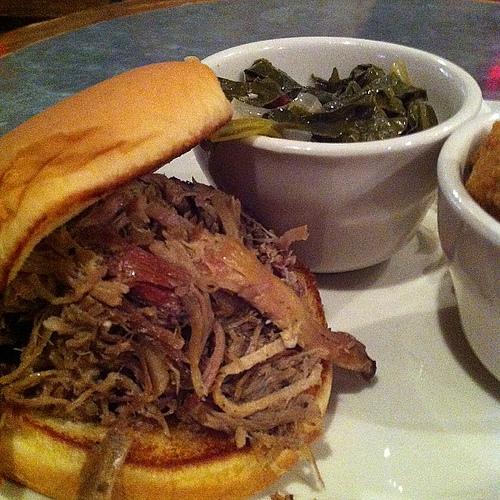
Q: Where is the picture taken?
A: Restaurant.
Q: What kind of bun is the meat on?
A: White.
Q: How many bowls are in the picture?
A: Two.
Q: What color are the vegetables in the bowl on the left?
A: Green.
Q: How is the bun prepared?
A: Toasted.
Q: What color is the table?
A: Blue.